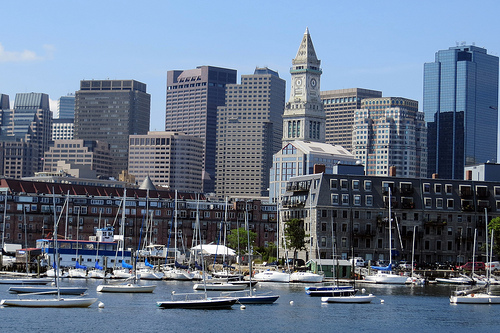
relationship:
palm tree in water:
[225, 224, 257, 258] [0, 269, 495, 331]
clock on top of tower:
[294, 75, 317, 94] [280, 26, 328, 141]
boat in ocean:
[321, 296, 376, 303] [0, 275, 499, 332]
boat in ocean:
[0, 298, 99, 308] [0, 275, 499, 332]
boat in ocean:
[96, 283, 157, 292] [0, 275, 499, 332]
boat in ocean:
[364, 273, 406, 284] [0, 275, 499, 332]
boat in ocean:
[449, 293, 499, 304] [0, 275, 499, 332]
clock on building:
[291, 76, 303, 87] [278, 25, 327, 147]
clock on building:
[310, 78, 317, 87] [278, 25, 327, 147]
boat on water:
[36, 224, 133, 275] [0, 269, 495, 331]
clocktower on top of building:
[280, 26, 325, 149] [269, 141, 366, 203]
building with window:
[213, 66, 286, 201] [236, 97, 243, 103]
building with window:
[213, 66, 286, 201] [246, 115, 253, 120]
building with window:
[213, 66, 286, 201] [256, 102, 262, 107]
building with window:
[213, 66, 286, 201] [257, 85, 263, 89]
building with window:
[213, 66, 286, 201] [229, 182, 236, 186]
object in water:
[157, 200, 276, 322] [0, 269, 495, 331]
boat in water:
[155, 299, 239, 308] [0, 269, 495, 331]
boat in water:
[321, 296, 376, 303] [0, 269, 495, 331]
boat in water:
[0, 298, 99, 308] [0, 269, 495, 331]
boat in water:
[96, 283, 157, 292] [0, 269, 495, 331]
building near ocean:
[273, 163, 397, 263] [0, 275, 499, 332]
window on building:
[320, 207, 339, 221] [319, 186, 495, 251]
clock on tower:
[295, 79, 303, 87] [280, 29, 330, 135]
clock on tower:
[307, 77, 319, 91] [280, 29, 330, 135]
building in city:
[423, 45, 498, 196] [2, 27, 497, 244]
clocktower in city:
[275, 23, 349, 251] [39, 24, 479, 319]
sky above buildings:
[9, 9, 482, 111] [9, 32, 483, 206]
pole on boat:
[47, 197, 67, 297] [2, 292, 103, 313]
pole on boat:
[380, 180, 396, 270] [361, 267, 419, 285]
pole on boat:
[467, 225, 482, 282] [444, 289, 499, 309]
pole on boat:
[166, 185, 183, 270] [154, 296, 240, 313]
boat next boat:
[446, 289, 498, 308] [433, 271, 497, 284]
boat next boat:
[433, 271, 497, 284] [321, 296, 376, 303]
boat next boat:
[321, 296, 376, 303] [155, 299, 239, 308]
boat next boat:
[155, 299, 239, 308] [1, 295, 95, 307]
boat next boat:
[0, 293, 104, 315] [99, 280, 160, 297]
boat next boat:
[99, 280, 160, 297] [155, 299, 239, 308]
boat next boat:
[155, 299, 239, 308] [321, 296, 376, 303]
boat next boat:
[321, 296, 376, 303] [449, 286, 497, 309]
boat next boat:
[321, 296, 376, 303] [302, 276, 362, 296]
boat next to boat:
[231, 289, 280, 310] [158, 288, 238, 309]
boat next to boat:
[187, 278, 256, 295] [314, 282, 360, 294]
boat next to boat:
[155, 299, 239, 308] [7, 292, 99, 311]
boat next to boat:
[306, 285, 354, 296] [321, 296, 376, 303]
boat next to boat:
[321, 296, 376, 303] [154, 295, 236, 307]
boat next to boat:
[154, 295, 236, 307] [98, 284, 159, 295]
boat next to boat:
[449, 293, 499, 304] [306, 285, 354, 296]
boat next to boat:
[324, 239, 376, 305] [308, 209, 361, 295]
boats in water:
[4, 262, 498, 309] [260, 310, 349, 324]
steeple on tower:
[295, 28, 321, 63] [280, 62, 327, 172]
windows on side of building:
[187, 97, 192, 99] [165, 64, 236, 196]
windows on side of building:
[200, 111, 206, 114] [165, 64, 236, 196]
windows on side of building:
[182, 112, 190, 115] [165, 64, 236, 196]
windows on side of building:
[188, 96, 193, 98] [165, 64, 236, 196]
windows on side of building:
[207, 106, 215, 111] [165, 64, 236, 196]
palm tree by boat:
[225, 226, 260, 266] [193, 196, 250, 290]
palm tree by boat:
[225, 226, 260, 266] [253, 270, 290, 282]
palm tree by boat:
[225, 226, 260, 266] [287, 270, 323, 283]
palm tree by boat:
[225, 226, 260, 266] [95, 215, 157, 292]